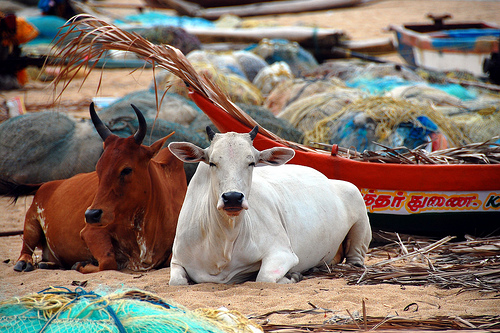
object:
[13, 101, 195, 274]
brown cow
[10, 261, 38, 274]
black hooves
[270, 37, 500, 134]
bags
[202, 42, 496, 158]
net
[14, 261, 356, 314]
ground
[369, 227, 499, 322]
sticks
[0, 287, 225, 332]
buoys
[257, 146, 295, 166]
cow's ear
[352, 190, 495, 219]
lettering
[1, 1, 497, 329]
beach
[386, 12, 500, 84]
boat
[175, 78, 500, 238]
boat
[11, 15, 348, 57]
boat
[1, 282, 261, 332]
fishing equipment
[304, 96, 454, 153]
fishing equipment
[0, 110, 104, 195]
fishing equipment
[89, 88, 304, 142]
fishing equipment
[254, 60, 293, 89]
fishing equipment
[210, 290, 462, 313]
sand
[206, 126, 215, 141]
horns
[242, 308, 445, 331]
twigs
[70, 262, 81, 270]
hoof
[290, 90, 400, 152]
nets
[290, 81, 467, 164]
buoys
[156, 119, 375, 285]
bull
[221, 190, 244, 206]
black nose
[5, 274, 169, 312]
netting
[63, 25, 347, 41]
pole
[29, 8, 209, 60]
fabric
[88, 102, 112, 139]
horns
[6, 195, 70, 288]
sand